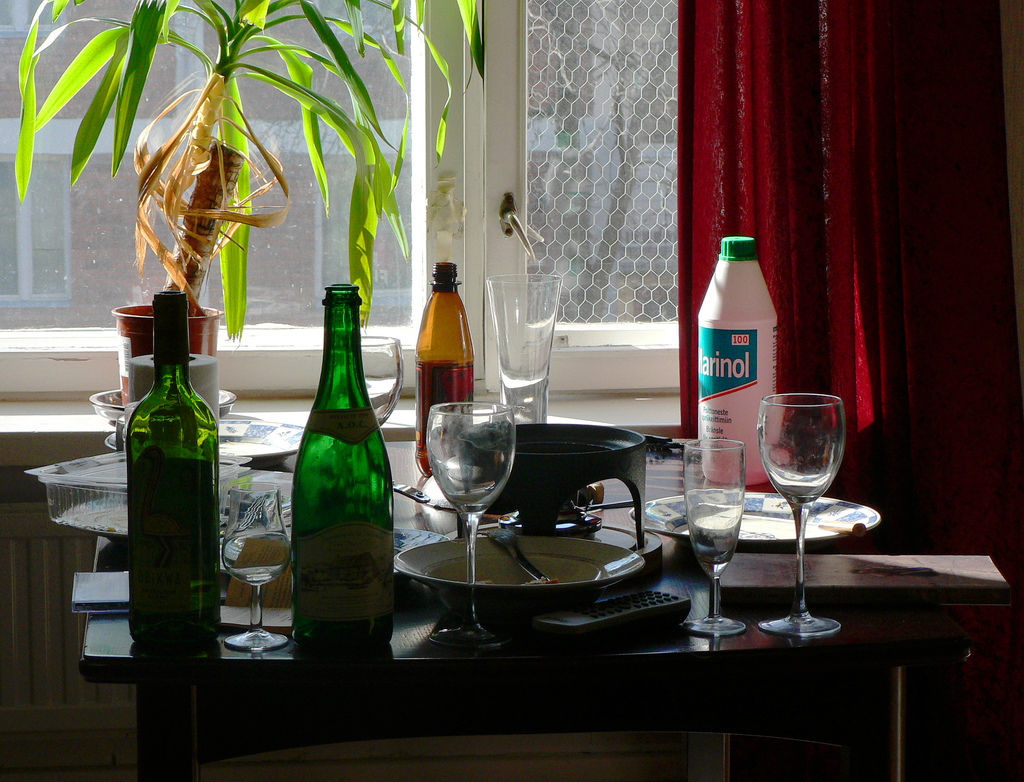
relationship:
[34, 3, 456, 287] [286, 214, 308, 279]
plant in  the window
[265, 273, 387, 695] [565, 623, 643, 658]
bottle on the table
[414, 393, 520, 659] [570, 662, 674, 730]
glass on the table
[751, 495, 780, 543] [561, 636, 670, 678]
plate on the table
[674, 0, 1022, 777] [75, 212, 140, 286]
curtain on the window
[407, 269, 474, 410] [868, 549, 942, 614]
bottle on the table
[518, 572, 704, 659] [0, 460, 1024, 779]
remote on table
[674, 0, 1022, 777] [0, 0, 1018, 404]
curtain on window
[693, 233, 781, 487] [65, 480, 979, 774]
bottle on table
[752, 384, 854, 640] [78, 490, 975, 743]
wine glass on table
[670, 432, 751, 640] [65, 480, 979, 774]
glass on table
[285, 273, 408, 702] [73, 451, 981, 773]
bottle on table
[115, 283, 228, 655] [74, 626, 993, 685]
bottle on edge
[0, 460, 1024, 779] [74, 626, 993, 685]
table has edge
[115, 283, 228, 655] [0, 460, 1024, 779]
bottle on table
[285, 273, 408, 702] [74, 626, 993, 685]
bottle on edge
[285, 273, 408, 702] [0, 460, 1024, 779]
bottle on table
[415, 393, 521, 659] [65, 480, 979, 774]
glass on table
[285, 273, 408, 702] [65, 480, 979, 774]
bottle on table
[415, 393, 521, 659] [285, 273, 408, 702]
glass next to bottle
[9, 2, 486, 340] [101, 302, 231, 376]
plant in pot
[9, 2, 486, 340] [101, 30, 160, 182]
plant has leaf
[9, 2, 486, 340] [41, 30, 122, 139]
plant has leaf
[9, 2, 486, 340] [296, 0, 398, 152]
plant has leaf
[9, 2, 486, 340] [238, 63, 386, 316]
plant has leaf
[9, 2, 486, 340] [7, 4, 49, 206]
plant has leaf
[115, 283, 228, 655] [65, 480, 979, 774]
bottle sitting on table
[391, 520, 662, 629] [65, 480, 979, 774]
plate sitting on table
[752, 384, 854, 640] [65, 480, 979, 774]
wine glass sitting on table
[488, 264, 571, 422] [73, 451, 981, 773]
glass sitting on table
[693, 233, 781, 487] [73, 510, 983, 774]
bottle sitting on table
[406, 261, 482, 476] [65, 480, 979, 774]
bottle sitting on table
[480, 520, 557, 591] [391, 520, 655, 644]
fork laying on plate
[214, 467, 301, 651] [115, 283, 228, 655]
glass sitting between bottle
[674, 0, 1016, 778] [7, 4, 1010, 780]
curtain hanging by window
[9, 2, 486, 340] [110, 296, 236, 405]
plant in pot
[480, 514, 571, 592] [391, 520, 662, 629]
fork on plate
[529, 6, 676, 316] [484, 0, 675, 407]
wire on window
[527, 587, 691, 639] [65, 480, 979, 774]
remote on table